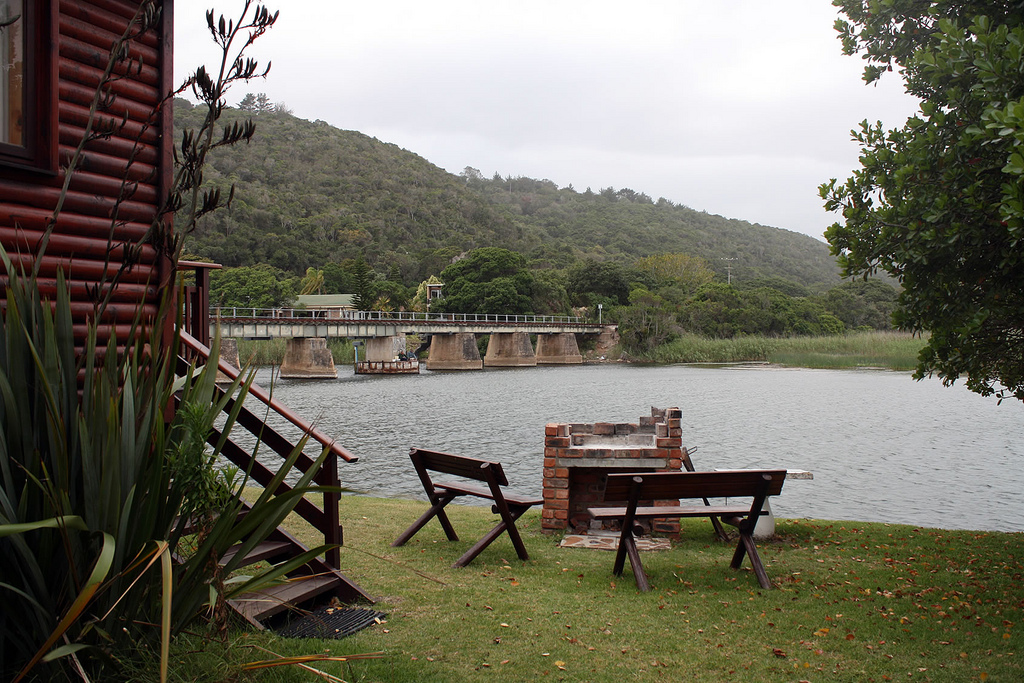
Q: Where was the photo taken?
A: At a lake.